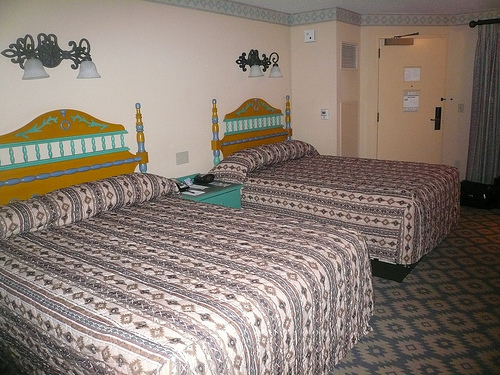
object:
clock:
[196, 168, 215, 185]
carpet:
[324, 204, 500, 373]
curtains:
[465, 20, 500, 186]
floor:
[321, 204, 500, 374]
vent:
[338, 38, 360, 70]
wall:
[337, 6, 360, 156]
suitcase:
[460, 179, 497, 210]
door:
[373, 34, 450, 169]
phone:
[174, 181, 189, 188]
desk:
[176, 172, 243, 212]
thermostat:
[318, 108, 330, 124]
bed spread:
[0, 171, 375, 374]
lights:
[243, 61, 268, 79]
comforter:
[0, 171, 374, 374]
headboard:
[0, 105, 148, 212]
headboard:
[212, 95, 291, 167]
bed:
[209, 139, 462, 282]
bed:
[0, 171, 375, 374]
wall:
[290, 7, 339, 157]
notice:
[400, 87, 424, 114]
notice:
[403, 65, 425, 81]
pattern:
[412, 317, 440, 333]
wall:
[0, 0, 294, 179]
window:
[479, 78, 500, 99]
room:
[0, 0, 500, 374]